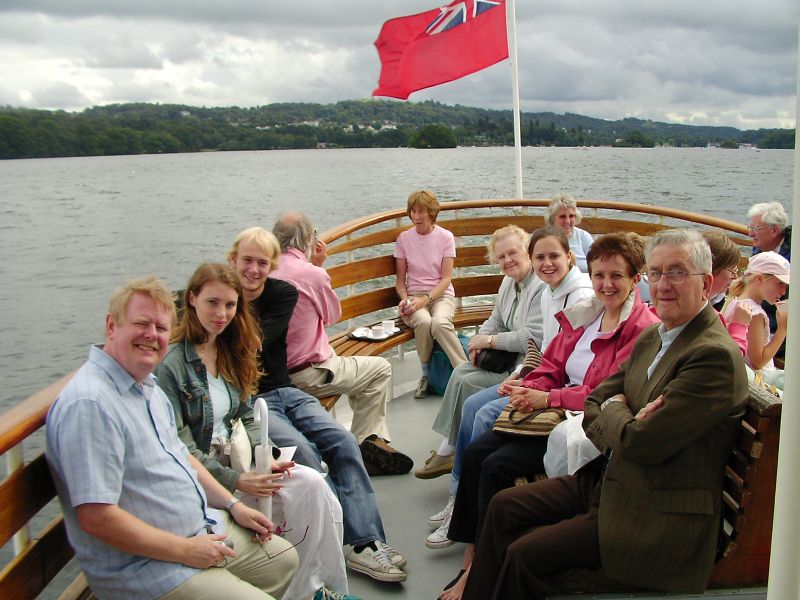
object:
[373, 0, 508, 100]
flag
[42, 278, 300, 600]
man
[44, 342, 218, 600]
shirt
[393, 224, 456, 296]
shirt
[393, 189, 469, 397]
lady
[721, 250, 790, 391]
girl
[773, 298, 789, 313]
drink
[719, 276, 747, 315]
pony tail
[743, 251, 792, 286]
cap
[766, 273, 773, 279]
visor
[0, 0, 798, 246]
outdoors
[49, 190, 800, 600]
people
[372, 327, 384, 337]
coffee mug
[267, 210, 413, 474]
man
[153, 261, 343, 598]
woman